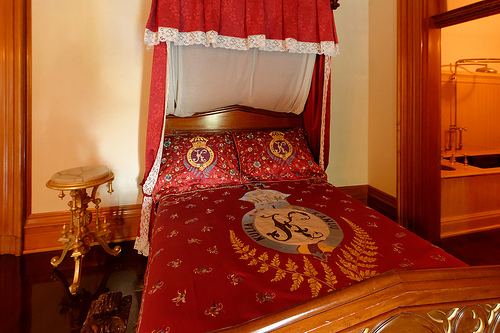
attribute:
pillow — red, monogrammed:
[156, 130, 245, 196]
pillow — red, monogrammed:
[230, 118, 329, 183]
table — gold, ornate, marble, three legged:
[42, 162, 126, 300]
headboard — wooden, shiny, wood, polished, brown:
[157, 99, 307, 137]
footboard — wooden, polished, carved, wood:
[192, 263, 498, 332]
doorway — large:
[414, 2, 500, 274]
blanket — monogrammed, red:
[135, 178, 466, 332]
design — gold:
[179, 135, 219, 180]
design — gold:
[263, 129, 299, 171]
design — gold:
[220, 185, 384, 299]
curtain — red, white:
[134, 0, 340, 260]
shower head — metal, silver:
[476, 62, 498, 78]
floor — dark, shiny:
[0, 242, 157, 331]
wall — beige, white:
[29, 2, 402, 213]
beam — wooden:
[425, 1, 500, 33]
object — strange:
[73, 289, 138, 332]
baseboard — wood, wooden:
[19, 199, 145, 255]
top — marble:
[46, 162, 113, 187]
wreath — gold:
[218, 212, 381, 301]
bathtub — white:
[439, 151, 498, 238]